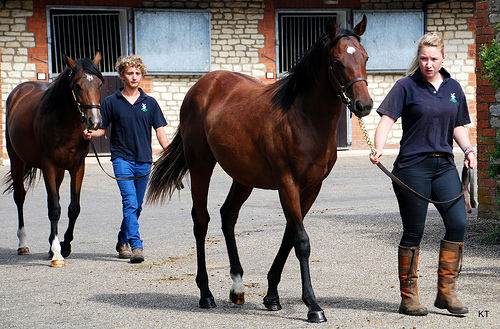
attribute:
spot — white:
[84, 72, 94, 82]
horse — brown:
[143, 13, 373, 323]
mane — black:
[266, 25, 359, 115]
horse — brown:
[1, 47, 113, 269]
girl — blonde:
[373, 23, 472, 320]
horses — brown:
[183, 57, 428, 283]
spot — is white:
[346, 44, 356, 54]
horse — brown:
[166, 37, 411, 282]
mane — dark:
[31, 59, 104, 165]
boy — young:
[84, 53, 184, 263]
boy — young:
[95, 65, 187, 276]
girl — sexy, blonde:
[366, 29, 475, 316]